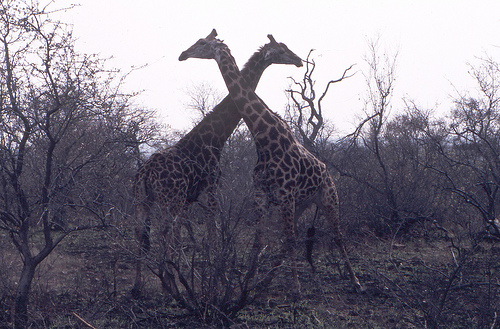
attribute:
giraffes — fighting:
[109, 25, 369, 304]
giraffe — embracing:
[129, 36, 269, 304]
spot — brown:
[284, 152, 292, 167]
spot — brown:
[302, 157, 310, 167]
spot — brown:
[304, 177, 315, 186]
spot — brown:
[283, 178, 295, 188]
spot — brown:
[260, 136, 268, 148]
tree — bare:
[451, 107, 497, 254]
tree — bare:
[355, 31, 420, 248]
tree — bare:
[290, 33, 345, 168]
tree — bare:
[97, 108, 144, 249]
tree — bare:
[1, 8, 96, 320]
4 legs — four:
[238, 192, 362, 298]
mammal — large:
[178, 27, 363, 297]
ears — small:
[207, 28, 221, 43]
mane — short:
[242, 51, 263, 77]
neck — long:
[211, 60, 287, 137]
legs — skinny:
[234, 184, 364, 299]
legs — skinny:
[128, 187, 218, 297]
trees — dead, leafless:
[4, 18, 216, 313]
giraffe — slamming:
[177, 27, 366, 299]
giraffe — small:
[113, 25, 310, 299]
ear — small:
[262, 31, 285, 51]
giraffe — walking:
[202, 48, 347, 242]